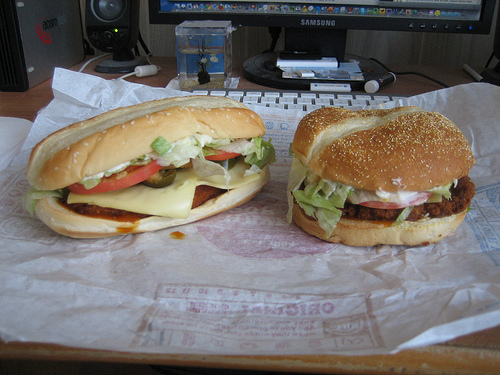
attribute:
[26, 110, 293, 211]
sandwich — brown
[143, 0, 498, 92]
television — on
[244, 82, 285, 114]
lettuce — small, green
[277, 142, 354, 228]
lettuce — green, small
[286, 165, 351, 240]
vegetable — green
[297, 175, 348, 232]
lettuce — green, small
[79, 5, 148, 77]
speaker — partially seen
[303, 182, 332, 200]
lettuce — small, green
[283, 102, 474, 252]
sandwich — brown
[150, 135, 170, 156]
lettuce — green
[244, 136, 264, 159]
lettuce — green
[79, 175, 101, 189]
lettuce — green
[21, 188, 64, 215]
lettuce — green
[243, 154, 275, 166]
lettuce — green